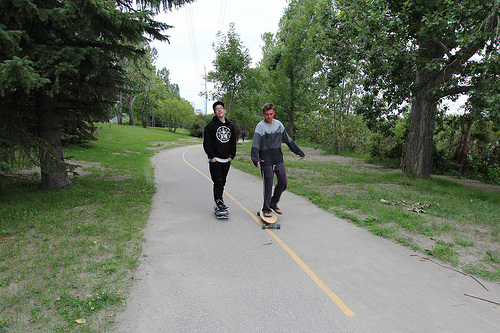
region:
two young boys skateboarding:
[201, 100, 306, 228]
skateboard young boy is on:
[258, 203, 281, 228]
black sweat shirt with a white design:
[200, 118, 236, 158]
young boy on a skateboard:
[248, 101, 305, 216]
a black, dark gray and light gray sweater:
[250, 118, 300, 156]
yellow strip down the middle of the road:
[173, 131, 358, 329]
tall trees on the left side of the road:
[198, 1, 494, 181]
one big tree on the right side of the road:
[0, 0, 200, 196]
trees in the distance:
[128, 88, 216, 136]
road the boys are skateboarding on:
[119, 144, 499, 331]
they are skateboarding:
[195, 78, 302, 240]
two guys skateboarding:
[182, 72, 318, 257]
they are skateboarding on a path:
[195, 82, 329, 229]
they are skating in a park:
[180, 72, 329, 239]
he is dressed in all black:
[192, 80, 239, 234]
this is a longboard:
[255, 201, 283, 233]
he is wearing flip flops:
[255, 201, 291, 226]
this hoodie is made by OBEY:
[202, 110, 240, 165]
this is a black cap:
[213, 93, 225, 108]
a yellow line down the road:
[177, 141, 364, 322]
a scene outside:
[9, 13, 499, 324]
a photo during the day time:
[12, 15, 494, 332]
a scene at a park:
[7, 8, 498, 329]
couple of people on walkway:
[179, 89, 321, 263]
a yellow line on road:
[160, 116, 370, 331]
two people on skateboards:
[177, 82, 327, 277]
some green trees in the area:
[6, 0, 498, 218]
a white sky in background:
[123, 1, 305, 143]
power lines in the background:
[172, 1, 259, 156]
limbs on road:
[397, 232, 494, 332]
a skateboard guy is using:
[253, 205, 282, 232]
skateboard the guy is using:
[211, 201, 232, 222]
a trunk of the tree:
[398, 103, 442, 179]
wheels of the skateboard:
[259, 221, 284, 232]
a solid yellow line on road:
[179, 143, 208, 187]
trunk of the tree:
[33, 136, 77, 196]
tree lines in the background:
[108, 14, 308, 130]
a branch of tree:
[432, 5, 496, 84]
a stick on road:
[461, 290, 499, 310]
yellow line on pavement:
[284, 246, 319, 281]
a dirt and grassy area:
[54, 233, 104, 285]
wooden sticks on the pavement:
[424, 247, 494, 306]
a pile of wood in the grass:
[377, 181, 447, 221]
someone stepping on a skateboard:
[254, 199, 282, 236]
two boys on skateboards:
[189, 91, 313, 236]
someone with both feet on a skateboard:
[205, 188, 239, 228]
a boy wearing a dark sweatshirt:
[190, 113, 245, 167]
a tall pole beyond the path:
[183, 56, 218, 111]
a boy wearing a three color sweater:
[246, 116, 307, 172]